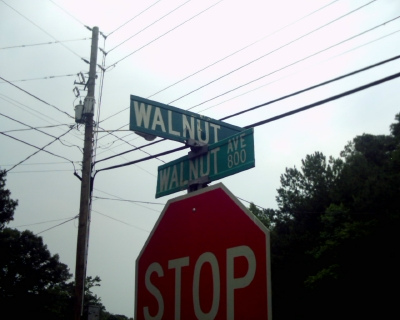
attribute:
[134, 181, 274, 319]
sign — red, white, octagon, stop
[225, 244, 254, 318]
p — white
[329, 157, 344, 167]
branch — tree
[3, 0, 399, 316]
sky — blue, white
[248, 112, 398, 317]
trees — green  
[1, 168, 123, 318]
trees — green  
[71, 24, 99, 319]
pole — brown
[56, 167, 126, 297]
power pole — tall, brown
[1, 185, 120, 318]
trees — green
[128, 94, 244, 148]
sign — green, white, top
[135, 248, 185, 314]
s — white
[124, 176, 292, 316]
stop sign — red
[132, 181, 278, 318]
stop sign — red, white, octagon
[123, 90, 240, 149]
sign — green, white, WALNUT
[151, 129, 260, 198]
sign — green, white, WALNUT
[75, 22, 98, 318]
post — electicity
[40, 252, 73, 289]
branch — tree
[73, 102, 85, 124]
bucket — transformer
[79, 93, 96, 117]
bucket — transformer